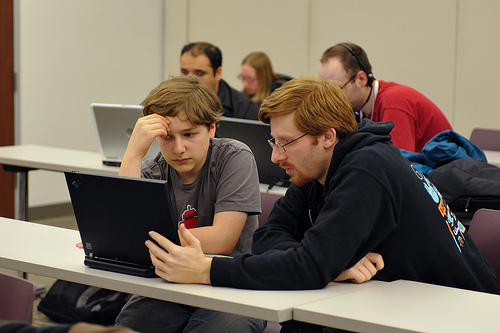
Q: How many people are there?
A: Five.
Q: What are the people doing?
A: Studying.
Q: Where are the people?
A: Classroom.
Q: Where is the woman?
A: Background.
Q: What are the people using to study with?
A: Computers.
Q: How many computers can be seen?
A: Three.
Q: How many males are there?
A: Four.